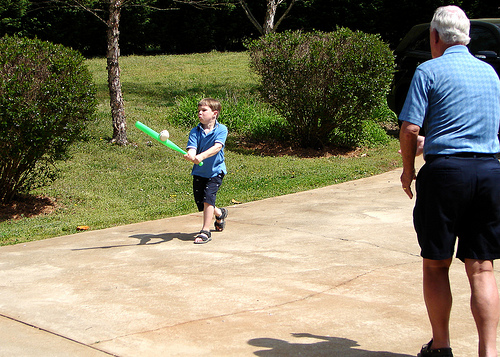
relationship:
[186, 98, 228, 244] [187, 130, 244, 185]
boy wears shirt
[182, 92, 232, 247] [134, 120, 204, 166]
boy holding baseball bat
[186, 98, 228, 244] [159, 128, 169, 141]
boy hitting ball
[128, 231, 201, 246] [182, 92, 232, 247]
shadow from boy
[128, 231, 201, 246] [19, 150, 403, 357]
shadow on driveway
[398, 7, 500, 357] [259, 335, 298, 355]
man has shadow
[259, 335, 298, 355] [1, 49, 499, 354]
shadow on ground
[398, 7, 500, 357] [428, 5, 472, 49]
man has hair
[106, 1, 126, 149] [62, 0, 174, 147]
tree trunk on tree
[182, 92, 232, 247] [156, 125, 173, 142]
boy hitting ball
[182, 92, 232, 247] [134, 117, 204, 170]
boy holding baseball bat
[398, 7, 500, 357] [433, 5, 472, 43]
man has hair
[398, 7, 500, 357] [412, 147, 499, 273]
man wearing blue shorts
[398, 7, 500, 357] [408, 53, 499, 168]
man wearing blue shirt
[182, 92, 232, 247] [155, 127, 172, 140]
boy hitting a ball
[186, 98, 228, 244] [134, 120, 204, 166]
boy holding baseball bat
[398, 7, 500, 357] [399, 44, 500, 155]
man wearing a blue shirt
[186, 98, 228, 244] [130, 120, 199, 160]
boy swinging a bat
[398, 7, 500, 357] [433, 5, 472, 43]
man with hair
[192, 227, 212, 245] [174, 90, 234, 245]
left foot of boy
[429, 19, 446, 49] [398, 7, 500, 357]
ear of man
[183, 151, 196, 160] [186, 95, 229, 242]
boy's hand of boy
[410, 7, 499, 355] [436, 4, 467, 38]
man has hair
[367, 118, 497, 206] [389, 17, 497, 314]
hand of a man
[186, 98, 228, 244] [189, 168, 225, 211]
boy has shorts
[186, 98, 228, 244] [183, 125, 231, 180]
boy has shirt